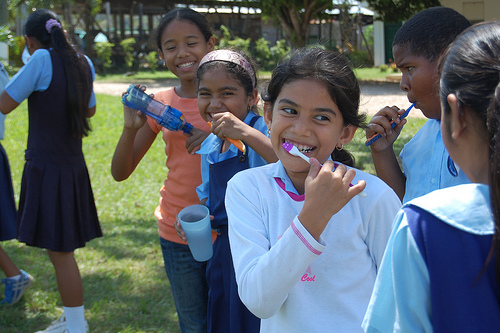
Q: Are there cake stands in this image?
A: No, there are no cake stands.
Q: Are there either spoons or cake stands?
A: No, there are no cake stands or spoons.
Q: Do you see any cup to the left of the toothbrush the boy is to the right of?
A: Yes, there are cups to the left of the toothbrush.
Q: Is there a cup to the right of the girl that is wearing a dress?
A: Yes, there are cups to the right of the girl.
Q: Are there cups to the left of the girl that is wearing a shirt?
A: Yes, there are cups to the left of the girl.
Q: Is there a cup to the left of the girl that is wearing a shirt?
A: Yes, there are cups to the left of the girl.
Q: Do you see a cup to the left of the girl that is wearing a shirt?
A: Yes, there are cups to the left of the girl.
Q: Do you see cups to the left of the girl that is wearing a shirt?
A: Yes, there are cups to the left of the girl.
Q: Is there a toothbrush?
A: Yes, there is a toothbrush.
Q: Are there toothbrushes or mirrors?
A: Yes, there is a toothbrush.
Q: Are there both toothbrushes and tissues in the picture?
A: No, there is a toothbrush but no tissues.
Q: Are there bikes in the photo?
A: No, there are no bikes.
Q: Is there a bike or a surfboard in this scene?
A: No, there are no bikes or surfboards.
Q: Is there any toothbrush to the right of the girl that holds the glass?
A: Yes, there is a toothbrush to the right of the girl.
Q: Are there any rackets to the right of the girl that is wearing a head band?
A: No, there is a toothbrush to the right of the girl.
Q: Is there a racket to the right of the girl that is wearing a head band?
A: No, there is a toothbrush to the right of the girl.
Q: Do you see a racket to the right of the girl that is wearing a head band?
A: No, there is a toothbrush to the right of the girl.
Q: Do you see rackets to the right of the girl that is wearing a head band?
A: No, there is a toothbrush to the right of the girl.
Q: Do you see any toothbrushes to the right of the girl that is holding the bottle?
A: Yes, there is a toothbrush to the right of the girl.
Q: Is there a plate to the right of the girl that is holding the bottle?
A: No, there is a toothbrush to the right of the girl.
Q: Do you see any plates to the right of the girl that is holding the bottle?
A: No, there is a toothbrush to the right of the girl.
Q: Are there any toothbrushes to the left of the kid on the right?
A: Yes, there is a toothbrush to the left of the kid.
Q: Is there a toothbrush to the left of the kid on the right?
A: Yes, there is a toothbrush to the left of the kid.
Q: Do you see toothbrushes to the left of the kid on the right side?
A: Yes, there is a toothbrush to the left of the kid.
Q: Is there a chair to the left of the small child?
A: No, there is a toothbrush to the left of the kid.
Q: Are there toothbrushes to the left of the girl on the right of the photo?
A: Yes, there is a toothbrush to the left of the girl.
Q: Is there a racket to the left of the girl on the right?
A: No, there is a toothbrush to the left of the girl.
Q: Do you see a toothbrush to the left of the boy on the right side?
A: Yes, there is a toothbrush to the left of the boy.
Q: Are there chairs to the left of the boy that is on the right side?
A: No, there is a toothbrush to the left of the boy.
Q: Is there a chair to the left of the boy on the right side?
A: No, there is a toothbrush to the left of the boy.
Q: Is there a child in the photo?
A: Yes, there are children.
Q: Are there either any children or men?
A: Yes, there are children.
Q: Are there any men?
A: No, there are no men.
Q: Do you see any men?
A: No, there are no men.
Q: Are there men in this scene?
A: No, there are no men.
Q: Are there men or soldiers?
A: No, there are no men or soldiers.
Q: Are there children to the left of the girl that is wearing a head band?
A: Yes, there are children to the left of the girl.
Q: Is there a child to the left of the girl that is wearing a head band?
A: Yes, there are children to the left of the girl.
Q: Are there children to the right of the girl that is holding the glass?
A: No, the children are to the left of the girl.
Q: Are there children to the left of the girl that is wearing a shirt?
A: Yes, there are children to the left of the girl.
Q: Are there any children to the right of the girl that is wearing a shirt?
A: No, the children are to the left of the girl.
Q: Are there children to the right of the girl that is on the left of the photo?
A: Yes, there are children to the right of the girl.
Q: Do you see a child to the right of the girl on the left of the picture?
A: Yes, there are children to the right of the girl.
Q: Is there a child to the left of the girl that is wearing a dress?
A: No, the children are to the right of the girl.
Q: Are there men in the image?
A: No, there are no men.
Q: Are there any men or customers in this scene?
A: No, there are no men or customers.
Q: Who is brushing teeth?
A: The girl is brushing teeth.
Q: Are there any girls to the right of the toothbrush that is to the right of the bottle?
A: Yes, there is a girl to the right of the toothbrush.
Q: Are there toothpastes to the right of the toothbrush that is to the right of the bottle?
A: No, there is a girl to the right of the toothbrush.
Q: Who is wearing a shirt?
A: The girl is wearing a shirt.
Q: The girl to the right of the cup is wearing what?
A: The girl is wearing a shirt.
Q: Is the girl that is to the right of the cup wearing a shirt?
A: Yes, the girl is wearing a shirt.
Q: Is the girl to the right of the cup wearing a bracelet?
A: No, the girl is wearing a shirt.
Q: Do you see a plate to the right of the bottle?
A: No, there is a girl to the right of the bottle.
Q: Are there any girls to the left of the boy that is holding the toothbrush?
A: Yes, there is a girl to the left of the boy.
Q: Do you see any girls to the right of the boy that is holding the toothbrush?
A: No, the girl is to the left of the boy.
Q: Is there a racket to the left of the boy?
A: No, there is a girl to the left of the boy.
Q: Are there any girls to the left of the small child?
A: Yes, there is a girl to the left of the child.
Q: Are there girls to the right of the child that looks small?
A: No, the girl is to the left of the child.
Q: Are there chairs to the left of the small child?
A: No, there is a girl to the left of the kid.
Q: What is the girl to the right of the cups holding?
A: The girl is holding the toothbrush.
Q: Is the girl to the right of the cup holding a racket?
A: No, the girl is holding the toothbrush.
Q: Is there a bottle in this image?
A: Yes, there is a bottle.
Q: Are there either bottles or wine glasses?
A: Yes, there is a bottle.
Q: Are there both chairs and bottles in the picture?
A: No, there is a bottle but no chairs.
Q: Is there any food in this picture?
A: No, there is no food.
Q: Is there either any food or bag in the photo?
A: No, there are no food or bags.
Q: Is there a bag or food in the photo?
A: No, there are no food or bags.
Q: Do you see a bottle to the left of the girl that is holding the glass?
A: Yes, there is a bottle to the left of the girl.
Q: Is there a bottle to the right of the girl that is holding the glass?
A: No, the bottle is to the left of the girl.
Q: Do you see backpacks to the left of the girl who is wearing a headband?
A: No, there is a bottle to the left of the girl.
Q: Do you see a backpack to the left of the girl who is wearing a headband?
A: No, there is a bottle to the left of the girl.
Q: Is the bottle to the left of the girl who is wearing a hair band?
A: Yes, the bottle is to the left of the girl.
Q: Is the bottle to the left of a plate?
A: No, the bottle is to the left of the girl.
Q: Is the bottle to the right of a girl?
A: No, the bottle is to the left of a girl.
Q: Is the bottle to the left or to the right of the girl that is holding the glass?
A: The bottle is to the left of the girl.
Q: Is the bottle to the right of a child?
A: No, the bottle is to the left of a child.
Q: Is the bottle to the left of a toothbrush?
A: Yes, the bottle is to the left of a toothbrush.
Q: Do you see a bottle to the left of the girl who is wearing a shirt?
A: Yes, there is a bottle to the left of the girl.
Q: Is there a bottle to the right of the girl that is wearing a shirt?
A: No, the bottle is to the left of the girl.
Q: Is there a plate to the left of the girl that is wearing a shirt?
A: No, there is a bottle to the left of the girl.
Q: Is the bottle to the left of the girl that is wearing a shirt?
A: Yes, the bottle is to the left of the girl.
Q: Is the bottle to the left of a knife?
A: No, the bottle is to the left of the girl.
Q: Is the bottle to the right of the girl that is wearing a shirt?
A: No, the bottle is to the left of the girl.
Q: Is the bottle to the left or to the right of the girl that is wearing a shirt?
A: The bottle is to the left of the girl.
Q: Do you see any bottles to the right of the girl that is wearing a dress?
A: Yes, there is a bottle to the right of the girl.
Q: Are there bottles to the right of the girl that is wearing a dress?
A: Yes, there is a bottle to the right of the girl.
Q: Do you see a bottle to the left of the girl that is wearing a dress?
A: No, the bottle is to the right of the girl.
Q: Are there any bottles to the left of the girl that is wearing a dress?
A: No, the bottle is to the right of the girl.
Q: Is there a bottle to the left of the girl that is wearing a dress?
A: No, the bottle is to the right of the girl.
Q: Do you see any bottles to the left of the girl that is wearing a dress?
A: No, the bottle is to the right of the girl.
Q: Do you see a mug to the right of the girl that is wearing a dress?
A: No, there is a bottle to the right of the girl.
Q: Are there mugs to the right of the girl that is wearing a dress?
A: No, there is a bottle to the right of the girl.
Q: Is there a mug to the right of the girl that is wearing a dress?
A: No, there is a bottle to the right of the girl.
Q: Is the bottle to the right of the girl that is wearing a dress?
A: Yes, the bottle is to the right of the girl.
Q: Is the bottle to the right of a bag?
A: No, the bottle is to the right of the girl.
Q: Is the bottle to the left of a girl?
A: No, the bottle is to the right of a girl.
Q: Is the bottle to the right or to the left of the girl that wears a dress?
A: The bottle is to the right of the girl.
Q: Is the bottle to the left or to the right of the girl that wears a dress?
A: The bottle is to the right of the girl.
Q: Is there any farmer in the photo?
A: No, there are no farmers.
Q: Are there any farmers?
A: No, there are no farmers.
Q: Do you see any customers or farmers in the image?
A: No, there are no farmers or customers.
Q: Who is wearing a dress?
A: The girl is wearing a dress.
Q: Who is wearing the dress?
A: The girl is wearing a dress.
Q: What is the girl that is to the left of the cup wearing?
A: The girl is wearing a dress.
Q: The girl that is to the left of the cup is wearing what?
A: The girl is wearing a dress.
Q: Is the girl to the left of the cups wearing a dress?
A: Yes, the girl is wearing a dress.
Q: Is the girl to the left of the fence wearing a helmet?
A: No, the girl is wearing a dress.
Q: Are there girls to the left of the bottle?
A: Yes, there is a girl to the left of the bottle.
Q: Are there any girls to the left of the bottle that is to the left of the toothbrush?
A: Yes, there is a girl to the left of the bottle.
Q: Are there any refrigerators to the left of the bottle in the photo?
A: No, there is a girl to the left of the bottle.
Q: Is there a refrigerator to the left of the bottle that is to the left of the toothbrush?
A: No, there is a girl to the left of the bottle.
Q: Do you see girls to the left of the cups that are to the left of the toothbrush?
A: Yes, there is a girl to the left of the cups.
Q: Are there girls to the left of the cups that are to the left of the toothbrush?
A: Yes, there is a girl to the left of the cups.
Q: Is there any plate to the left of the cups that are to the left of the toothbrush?
A: No, there is a girl to the left of the cups.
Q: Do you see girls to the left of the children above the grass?
A: Yes, there is a girl to the left of the children.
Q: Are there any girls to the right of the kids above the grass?
A: No, the girl is to the left of the children.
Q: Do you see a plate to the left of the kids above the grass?
A: No, there is a girl to the left of the children.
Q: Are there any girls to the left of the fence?
A: Yes, there is a girl to the left of the fence.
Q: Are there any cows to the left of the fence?
A: No, there is a girl to the left of the fence.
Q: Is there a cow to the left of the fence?
A: No, there is a girl to the left of the fence.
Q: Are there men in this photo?
A: No, there are no men.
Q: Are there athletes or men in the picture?
A: No, there are no men or athletes.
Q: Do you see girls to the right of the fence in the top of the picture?
A: Yes, there is a girl to the right of the fence.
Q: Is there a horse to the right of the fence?
A: No, there is a girl to the right of the fence.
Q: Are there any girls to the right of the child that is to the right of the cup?
A: Yes, there is a girl to the right of the kid.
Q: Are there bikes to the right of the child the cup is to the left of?
A: No, there is a girl to the right of the kid.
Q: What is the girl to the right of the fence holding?
A: The girl is holding the toothbrush.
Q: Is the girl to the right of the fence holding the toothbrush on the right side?
A: Yes, the girl is holding the toothbrush.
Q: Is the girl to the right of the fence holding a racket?
A: No, the girl is holding the toothbrush.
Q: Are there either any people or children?
A: Yes, there is a child.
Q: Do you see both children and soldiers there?
A: No, there is a child but no soldiers.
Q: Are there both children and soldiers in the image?
A: No, there is a child but no soldiers.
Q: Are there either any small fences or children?
A: Yes, there is a small child.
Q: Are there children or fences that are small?
A: Yes, the child is small.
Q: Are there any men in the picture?
A: No, there are no men.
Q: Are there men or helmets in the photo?
A: No, there are no men or helmets.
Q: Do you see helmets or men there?
A: No, there are no men or helmets.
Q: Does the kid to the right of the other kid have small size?
A: Yes, the child is small.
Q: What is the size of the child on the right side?
A: The child is small.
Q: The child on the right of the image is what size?
A: The child is small.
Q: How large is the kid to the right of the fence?
A: The child is small.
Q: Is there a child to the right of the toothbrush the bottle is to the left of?
A: Yes, there is a child to the right of the toothbrush.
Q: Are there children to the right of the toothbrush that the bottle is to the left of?
A: Yes, there is a child to the right of the toothbrush.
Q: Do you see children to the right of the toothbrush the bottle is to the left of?
A: Yes, there is a child to the right of the toothbrush.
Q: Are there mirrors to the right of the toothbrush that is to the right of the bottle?
A: No, there is a child to the right of the toothbrush.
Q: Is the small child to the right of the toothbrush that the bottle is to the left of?
A: Yes, the child is to the right of the toothbrush.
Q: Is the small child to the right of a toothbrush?
A: Yes, the kid is to the right of a toothbrush.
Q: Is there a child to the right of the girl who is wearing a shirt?
A: Yes, there is a child to the right of the girl.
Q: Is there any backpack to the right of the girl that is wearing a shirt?
A: No, there is a child to the right of the girl.